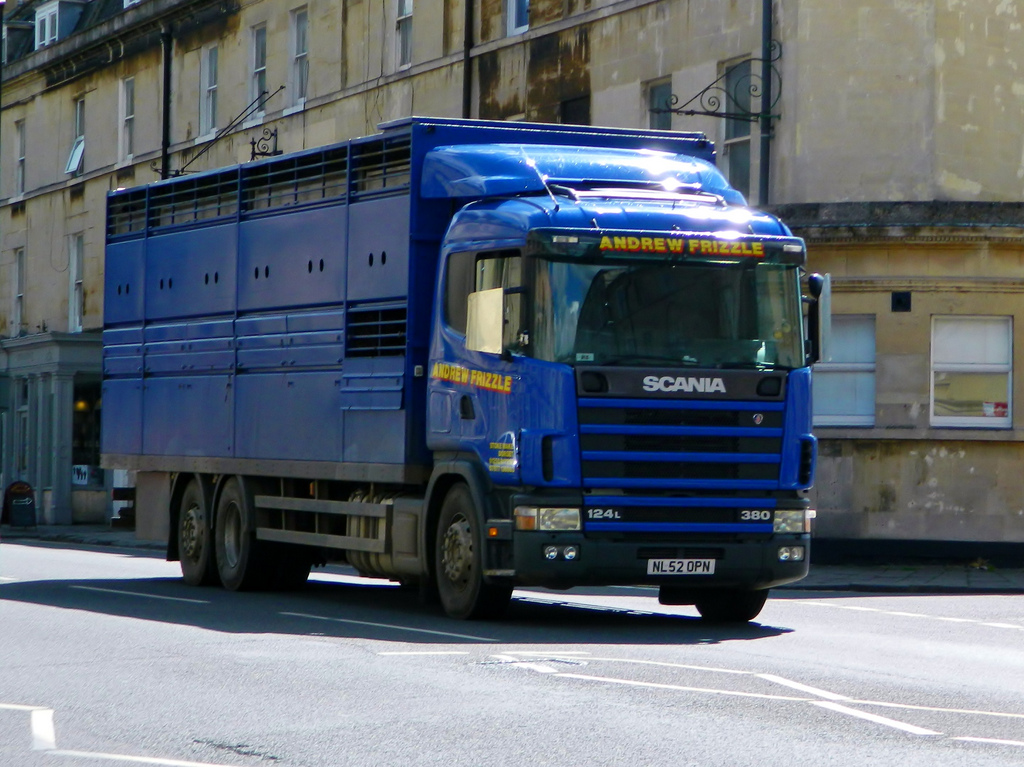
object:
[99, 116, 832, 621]
blue truck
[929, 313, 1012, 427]
white window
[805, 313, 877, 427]
white window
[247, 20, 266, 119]
white window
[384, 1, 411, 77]
white window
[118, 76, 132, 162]
white window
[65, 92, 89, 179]
white window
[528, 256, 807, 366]
window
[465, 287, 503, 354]
mirror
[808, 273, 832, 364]
mirror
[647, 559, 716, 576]
license plate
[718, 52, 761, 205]
window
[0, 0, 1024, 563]
building